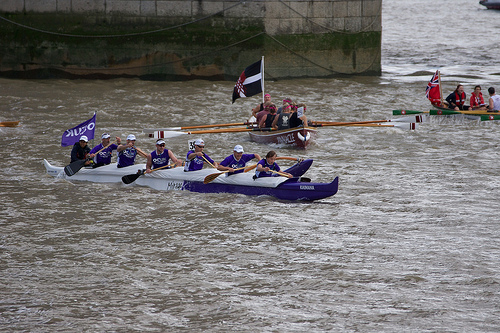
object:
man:
[218, 146, 258, 175]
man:
[184, 137, 215, 171]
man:
[146, 138, 184, 175]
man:
[116, 133, 148, 167]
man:
[88, 134, 119, 167]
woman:
[254, 149, 286, 177]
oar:
[149, 118, 260, 128]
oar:
[311, 119, 416, 132]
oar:
[308, 116, 430, 128]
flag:
[231, 55, 266, 104]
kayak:
[41, 157, 339, 203]